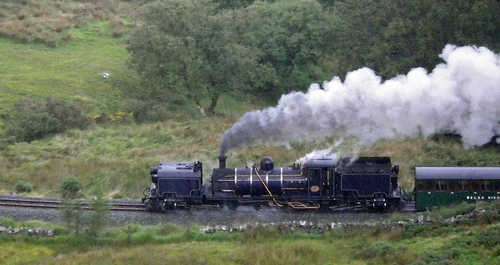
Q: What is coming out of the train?
A: Steam.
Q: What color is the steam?
A: White.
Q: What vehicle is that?
A: Train.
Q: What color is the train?
A: Black.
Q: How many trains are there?
A: One.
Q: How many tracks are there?
A: Just one.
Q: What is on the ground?
A: Grass.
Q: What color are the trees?
A: Green.